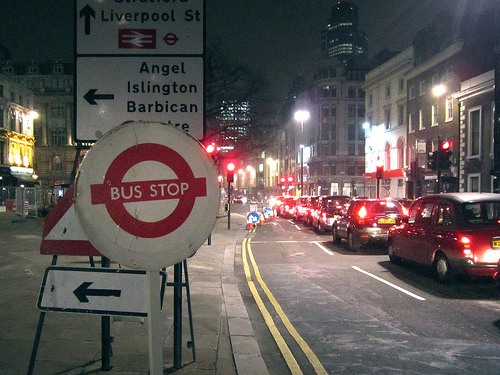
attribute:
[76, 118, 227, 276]
sign — white , red 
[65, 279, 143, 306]
arrow — black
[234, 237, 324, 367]
lines — yellow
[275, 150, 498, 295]
cars — stopped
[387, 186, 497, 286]
car — red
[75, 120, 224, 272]
bus stop — red, white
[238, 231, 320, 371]
lines — yellow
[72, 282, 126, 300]
arrow — black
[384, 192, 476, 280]
car — red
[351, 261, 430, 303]
line — white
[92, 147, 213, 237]
sign — red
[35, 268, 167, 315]
sign — black, white